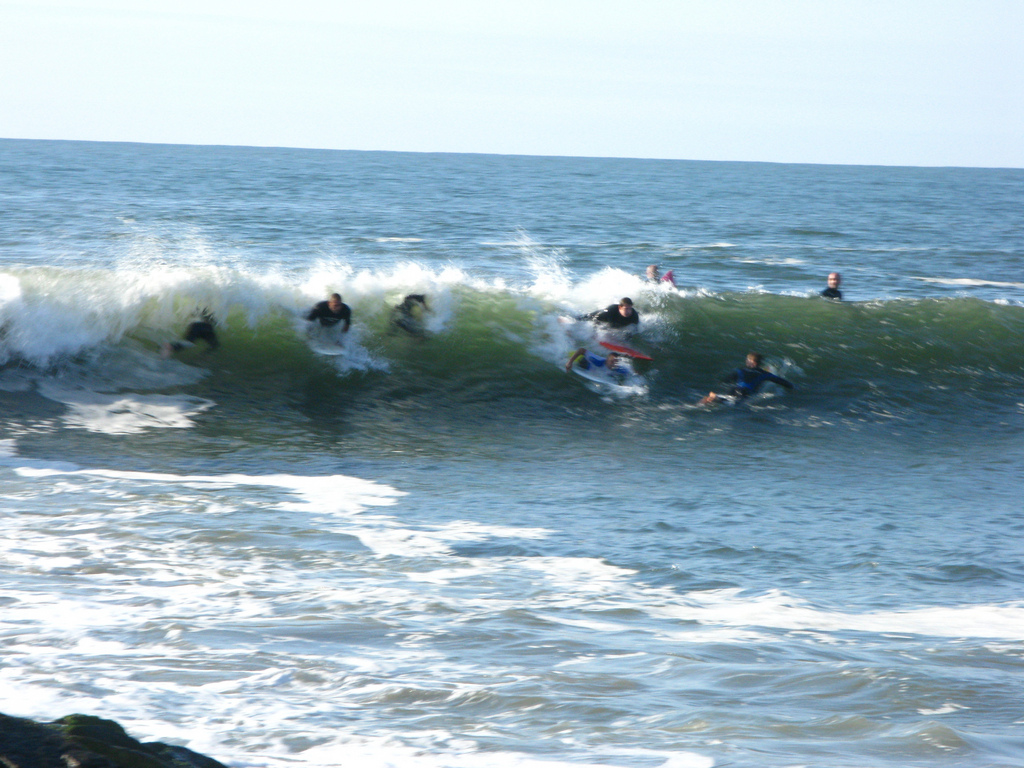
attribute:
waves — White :
[6, 173, 981, 470]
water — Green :
[49, 152, 933, 731]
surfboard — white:
[280, 329, 391, 379]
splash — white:
[133, 234, 477, 312]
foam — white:
[36, 346, 225, 459]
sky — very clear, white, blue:
[4, 7, 988, 163]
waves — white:
[0, 374, 983, 764]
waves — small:
[4, 232, 992, 455]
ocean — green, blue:
[8, 139, 992, 732]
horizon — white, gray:
[2, 128, 992, 208]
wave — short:
[4, 258, 785, 382]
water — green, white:
[4, 130, 992, 731]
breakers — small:
[10, 452, 622, 757]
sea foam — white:
[15, 262, 653, 362]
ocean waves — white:
[2, 204, 1020, 656]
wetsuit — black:
[717, 361, 791, 416]